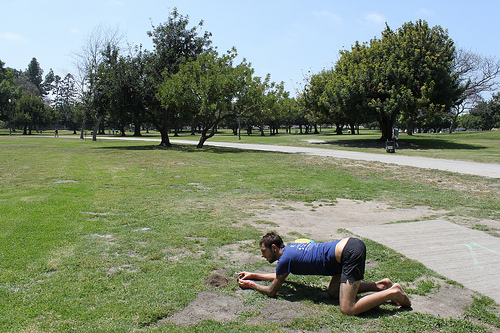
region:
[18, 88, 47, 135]
a green tree in a distance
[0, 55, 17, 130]
a green tree in a distance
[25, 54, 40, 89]
a green tree in a distance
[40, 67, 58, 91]
a green tree in a distance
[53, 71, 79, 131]
a green tree in a distance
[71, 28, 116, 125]
a green tree in a distance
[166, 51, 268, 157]
a green tree in a distance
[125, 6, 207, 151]
a green tree in a distance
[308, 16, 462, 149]
a green tree in a distance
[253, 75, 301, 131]
a green tree in a distance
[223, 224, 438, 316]
Man crawling on the ground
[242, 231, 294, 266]
Man is examining the dirt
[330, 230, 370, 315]
Man is wearing blue shorts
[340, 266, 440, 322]
No shoe on man's feet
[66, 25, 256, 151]
Full grown green trees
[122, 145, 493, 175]
Pathway to walk or bike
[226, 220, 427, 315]
Man looking at the ground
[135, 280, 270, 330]
Bare spots in the grass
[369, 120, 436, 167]
Man is pulling an object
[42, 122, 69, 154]
A person is taking a walk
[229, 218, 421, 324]
man kneeling on the ground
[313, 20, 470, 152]
green lush tree on the grass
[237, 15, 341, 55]
blue sky in the distance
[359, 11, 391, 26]
white cloud in the sky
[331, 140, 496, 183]
sidewalk path in the park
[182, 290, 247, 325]
patch of dirt in the grass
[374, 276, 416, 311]
feet of a man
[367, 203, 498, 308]
wood walkway into grass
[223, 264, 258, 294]
hands of a man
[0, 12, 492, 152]
green trees in the park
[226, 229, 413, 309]
this is a man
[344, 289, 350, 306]
the man is light skinned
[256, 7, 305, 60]
this is the sky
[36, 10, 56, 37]
the sky is blue in color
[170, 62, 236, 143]
this is a tree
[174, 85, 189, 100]
the tree has green leaves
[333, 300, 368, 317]
the knee is bent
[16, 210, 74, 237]
this is a grass area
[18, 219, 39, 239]
the grass is green in color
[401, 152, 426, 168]
this is a walking path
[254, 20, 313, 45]
the sky is blue in color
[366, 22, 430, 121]
this is a tree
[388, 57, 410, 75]
the tree has green leaves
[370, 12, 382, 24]
this is a cloud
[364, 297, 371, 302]
the man has a light skin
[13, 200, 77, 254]
this is a area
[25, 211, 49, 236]
the grass is green in color